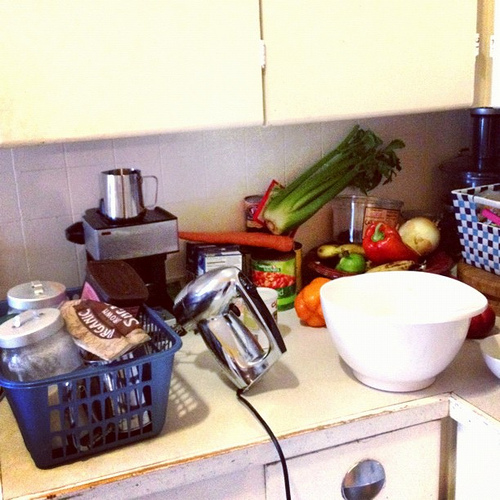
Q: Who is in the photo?
A: Noone.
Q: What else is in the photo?
A: Vegetables.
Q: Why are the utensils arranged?
A: They are clean.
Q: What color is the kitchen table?
A: White.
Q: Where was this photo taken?
A: In a kitchen.